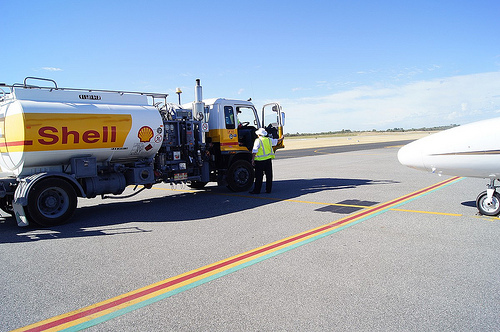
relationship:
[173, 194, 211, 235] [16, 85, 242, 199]
shadow of truck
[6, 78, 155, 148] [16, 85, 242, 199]
tank of truck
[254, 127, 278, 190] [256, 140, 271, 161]
man wearing vest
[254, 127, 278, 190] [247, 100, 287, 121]
man near door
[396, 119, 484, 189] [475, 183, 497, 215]
plane has wheel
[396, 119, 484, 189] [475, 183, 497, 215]
plane has tire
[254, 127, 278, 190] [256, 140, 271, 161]
man has vest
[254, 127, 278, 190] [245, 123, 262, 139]
man has hat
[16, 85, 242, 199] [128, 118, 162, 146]
truck has logo